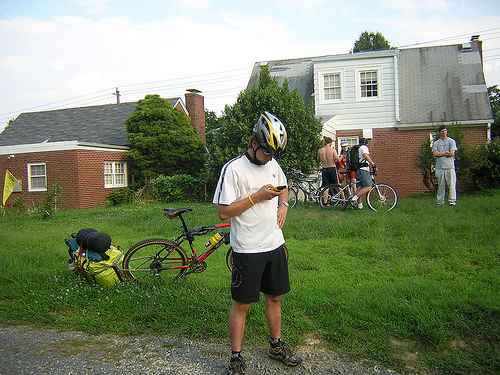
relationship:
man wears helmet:
[217, 109, 301, 373] [254, 104, 295, 162]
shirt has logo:
[199, 146, 302, 252] [269, 174, 277, 181]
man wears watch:
[217, 109, 301, 373] [274, 195, 295, 208]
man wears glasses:
[217, 109, 301, 373] [258, 141, 280, 160]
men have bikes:
[324, 133, 396, 217] [283, 179, 393, 214]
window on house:
[302, 65, 389, 120] [243, 48, 493, 215]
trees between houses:
[135, 82, 325, 213] [19, 27, 494, 205]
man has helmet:
[217, 109, 301, 373] [254, 104, 295, 162]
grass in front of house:
[307, 197, 499, 352] [243, 48, 493, 215]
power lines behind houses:
[127, 67, 254, 93] [19, 27, 494, 205]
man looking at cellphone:
[217, 109, 301, 373] [269, 182, 288, 194]